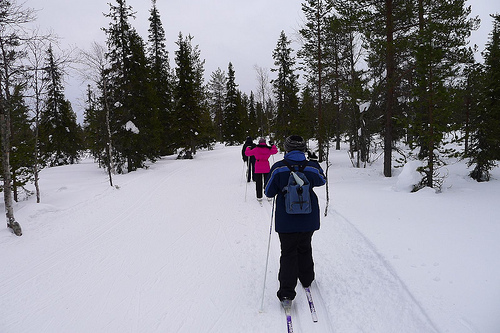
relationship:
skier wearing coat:
[242, 136, 278, 199] [245, 144, 278, 175]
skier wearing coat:
[263, 132, 328, 306] [265, 150, 328, 231]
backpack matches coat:
[282, 159, 312, 215] [265, 150, 328, 231]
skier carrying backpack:
[263, 132, 328, 306] [282, 159, 312, 215]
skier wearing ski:
[263, 132, 328, 306] [281, 309, 295, 332]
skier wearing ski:
[263, 132, 328, 306] [303, 286, 319, 323]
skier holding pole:
[263, 132, 328, 306] [260, 194, 277, 317]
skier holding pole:
[242, 136, 278, 199] [244, 157, 253, 200]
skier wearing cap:
[242, 136, 278, 199] [258, 137, 267, 144]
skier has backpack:
[263, 132, 328, 306] [282, 159, 312, 215]